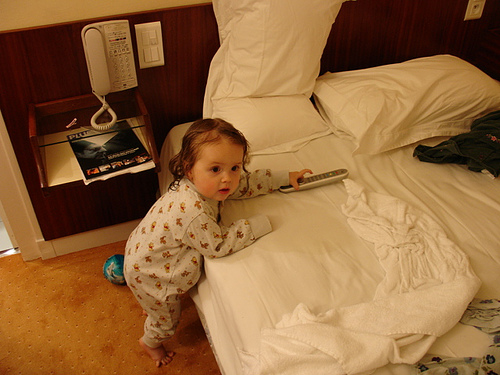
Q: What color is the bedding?
A: White.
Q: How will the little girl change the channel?
A: Remote.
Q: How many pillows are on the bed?
A: Two.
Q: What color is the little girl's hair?
A: Brown.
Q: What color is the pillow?
A: White.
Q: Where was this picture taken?
A: Hotel.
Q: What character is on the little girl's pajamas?
A: Winnie the pooh.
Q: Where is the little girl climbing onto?
A: Bed.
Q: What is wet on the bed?
A: Towel.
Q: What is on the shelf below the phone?
A: Magazine.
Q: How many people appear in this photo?
A: One.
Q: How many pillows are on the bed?
A: Two.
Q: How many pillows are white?
A: Two.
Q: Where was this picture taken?
A: Hotel room.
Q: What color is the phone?
A: White.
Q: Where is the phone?
A: On the wall.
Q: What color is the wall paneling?
A: Brown.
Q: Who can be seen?
A: A toddler.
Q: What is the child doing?
A: Grabbing a remote.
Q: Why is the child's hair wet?
A: It may have been bathed.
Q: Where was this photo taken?
A: In a hotel room.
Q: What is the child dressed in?
A: Pajamas.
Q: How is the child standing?
A: On tiptoes.